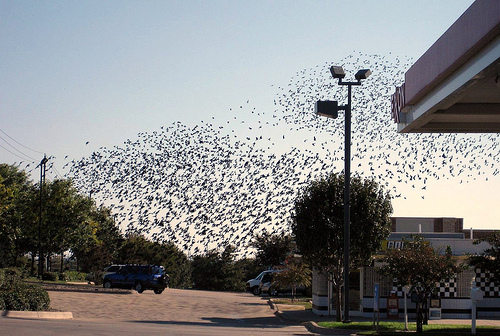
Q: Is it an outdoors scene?
A: Yes, it is outdoors.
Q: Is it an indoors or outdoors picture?
A: It is outdoors.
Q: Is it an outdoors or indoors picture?
A: It is outdoors.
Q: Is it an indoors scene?
A: No, it is outdoors.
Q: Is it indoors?
A: No, it is outdoors.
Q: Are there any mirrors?
A: No, there are no mirrors.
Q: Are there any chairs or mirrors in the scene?
A: No, there are no mirrors or chairs.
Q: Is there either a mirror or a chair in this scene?
A: No, there are no mirrors or chairs.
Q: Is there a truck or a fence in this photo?
A: No, there are no fences or trucks.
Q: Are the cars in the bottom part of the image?
A: Yes, the cars are in the bottom of the image.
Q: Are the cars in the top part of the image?
A: No, the cars are in the bottom of the image.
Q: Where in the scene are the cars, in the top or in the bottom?
A: The cars are in the bottom of the image.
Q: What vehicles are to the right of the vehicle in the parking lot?
A: The vehicles are cars.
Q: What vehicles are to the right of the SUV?
A: The vehicles are cars.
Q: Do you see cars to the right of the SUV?
A: Yes, there are cars to the right of the SUV.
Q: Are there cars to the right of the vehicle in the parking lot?
A: Yes, there are cars to the right of the SUV.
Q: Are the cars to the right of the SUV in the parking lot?
A: Yes, the cars are to the right of the SUV.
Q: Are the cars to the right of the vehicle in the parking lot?
A: Yes, the cars are to the right of the SUV.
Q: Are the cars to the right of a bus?
A: No, the cars are to the right of the SUV.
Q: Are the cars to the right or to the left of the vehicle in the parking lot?
A: The cars are to the right of the SUV.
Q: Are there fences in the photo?
A: No, there are no fences.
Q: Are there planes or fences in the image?
A: No, there are no fences or planes.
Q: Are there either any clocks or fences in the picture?
A: No, there are no fences or clocks.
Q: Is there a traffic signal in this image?
A: No, there are no traffic lights.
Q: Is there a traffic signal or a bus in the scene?
A: No, there are no traffic lights or buses.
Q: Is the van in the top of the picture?
A: No, the van is in the bottom of the image.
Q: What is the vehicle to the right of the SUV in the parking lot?
A: The vehicle is a van.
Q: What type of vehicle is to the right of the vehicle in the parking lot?
A: The vehicle is a van.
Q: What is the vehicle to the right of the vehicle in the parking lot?
A: The vehicle is a van.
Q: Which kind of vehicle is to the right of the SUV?
A: The vehicle is a van.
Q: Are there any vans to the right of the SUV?
A: Yes, there is a van to the right of the SUV.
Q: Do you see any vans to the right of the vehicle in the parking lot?
A: Yes, there is a van to the right of the SUV.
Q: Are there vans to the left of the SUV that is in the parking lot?
A: No, the van is to the right of the SUV.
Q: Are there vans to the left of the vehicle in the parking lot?
A: No, the van is to the right of the SUV.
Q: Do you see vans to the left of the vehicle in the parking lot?
A: No, the van is to the right of the SUV.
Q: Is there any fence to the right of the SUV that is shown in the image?
A: No, there is a van to the right of the SUV.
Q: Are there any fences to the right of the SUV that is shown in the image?
A: No, there is a van to the right of the SUV.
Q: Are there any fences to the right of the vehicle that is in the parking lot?
A: No, there is a van to the right of the SUV.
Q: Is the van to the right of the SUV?
A: Yes, the van is to the right of the SUV.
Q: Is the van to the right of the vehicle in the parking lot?
A: Yes, the van is to the right of the SUV.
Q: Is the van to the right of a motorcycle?
A: No, the van is to the right of the SUV.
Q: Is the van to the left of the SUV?
A: No, the van is to the right of the SUV.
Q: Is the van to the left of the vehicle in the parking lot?
A: No, the van is to the right of the SUV.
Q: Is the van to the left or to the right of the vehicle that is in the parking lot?
A: The van is to the right of the SUV.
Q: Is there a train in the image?
A: No, there are no trains.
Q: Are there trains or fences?
A: No, there are no trains or fences.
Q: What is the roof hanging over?
A: The roof is hanging over the parking lot.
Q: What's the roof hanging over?
A: The roof is hanging over the parking lot.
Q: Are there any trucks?
A: No, there are no trucks.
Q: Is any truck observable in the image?
A: No, there are no trucks.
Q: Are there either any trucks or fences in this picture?
A: No, there are no trucks or fences.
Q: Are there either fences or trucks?
A: No, there are no trucks or fences.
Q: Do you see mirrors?
A: No, there are no mirrors.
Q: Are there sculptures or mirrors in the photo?
A: No, there are no mirrors or sculptures.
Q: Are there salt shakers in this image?
A: No, there are no salt shakers.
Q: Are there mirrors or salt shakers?
A: No, there are no salt shakers or mirrors.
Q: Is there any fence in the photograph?
A: No, there are no fences.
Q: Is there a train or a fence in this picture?
A: No, there are no fences or trains.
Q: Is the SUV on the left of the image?
A: Yes, the SUV is on the left of the image.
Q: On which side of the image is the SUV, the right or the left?
A: The SUV is on the left of the image.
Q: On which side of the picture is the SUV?
A: The SUV is on the left of the image.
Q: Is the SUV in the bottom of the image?
A: Yes, the SUV is in the bottom of the image.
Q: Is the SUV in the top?
A: No, the SUV is in the bottom of the image.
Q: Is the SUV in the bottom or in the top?
A: The SUV is in the bottom of the image.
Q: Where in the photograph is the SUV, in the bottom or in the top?
A: The SUV is in the bottom of the image.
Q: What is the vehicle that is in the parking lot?
A: The vehicle is a SUV.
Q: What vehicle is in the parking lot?
A: The vehicle is a SUV.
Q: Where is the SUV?
A: The SUV is in the parking lot.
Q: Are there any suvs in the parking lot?
A: Yes, there is a SUV in the parking lot.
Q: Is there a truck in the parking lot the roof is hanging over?
A: No, there is a SUV in the parking lot.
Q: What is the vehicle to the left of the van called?
A: The vehicle is a SUV.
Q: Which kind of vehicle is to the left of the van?
A: The vehicle is a SUV.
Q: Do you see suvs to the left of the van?
A: Yes, there is a SUV to the left of the van.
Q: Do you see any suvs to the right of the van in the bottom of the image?
A: No, the SUV is to the left of the van.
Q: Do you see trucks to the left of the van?
A: No, there is a SUV to the left of the van.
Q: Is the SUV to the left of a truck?
A: No, the SUV is to the left of a van.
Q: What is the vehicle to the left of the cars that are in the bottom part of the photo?
A: The vehicle is a SUV.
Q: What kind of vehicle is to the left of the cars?
A: The vehicle is a SUV.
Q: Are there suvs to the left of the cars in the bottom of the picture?
A: Yes, there is a SUV to the left of the cars.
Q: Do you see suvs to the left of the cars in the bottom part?
A: Yes, there is a SUV to the left of the cars.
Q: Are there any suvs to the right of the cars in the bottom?
A: No, the SUV is to the left of the cars.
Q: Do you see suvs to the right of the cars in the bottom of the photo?
A: No, the SUV is to the left of the cars.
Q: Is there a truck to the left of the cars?
A: No, there is a SUV to the left of the cars.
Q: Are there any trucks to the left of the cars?
A: No, there is a SUV to the left of the cars.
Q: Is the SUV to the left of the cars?
A: Yes, the SUV is to the left of the cars.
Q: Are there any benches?
A: No, there are no benches.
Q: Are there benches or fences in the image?
A: No, there are no benches or fences.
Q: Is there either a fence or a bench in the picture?
A: No, there are no benches or fences.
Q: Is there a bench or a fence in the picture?
A: No, there are no benches or fences.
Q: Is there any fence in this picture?
A: No, there are no fences.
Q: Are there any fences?
A: No, there are no fences.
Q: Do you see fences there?
A: No, there are no fences.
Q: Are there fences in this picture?
A: No, there are no fences.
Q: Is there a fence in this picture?
A: No, there are no fences.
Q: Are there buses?
A: No, there are no buses.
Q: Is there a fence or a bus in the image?
A: No, there are no buses or fences.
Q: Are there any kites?
A: No, there are no kites.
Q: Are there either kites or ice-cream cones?
A: No, there are no kites or ice-cream cones.